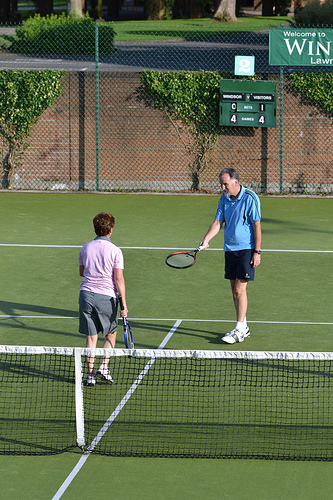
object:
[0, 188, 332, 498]
court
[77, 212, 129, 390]
woman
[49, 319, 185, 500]
line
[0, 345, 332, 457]
net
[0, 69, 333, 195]
wall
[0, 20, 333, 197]
fence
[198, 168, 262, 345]
man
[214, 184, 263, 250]
blue shirt